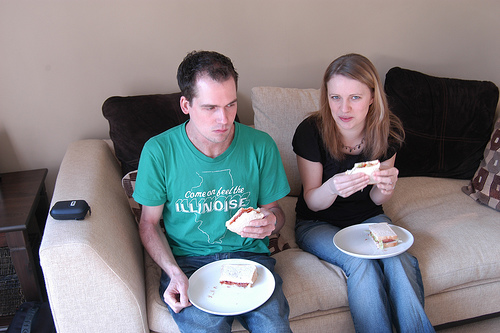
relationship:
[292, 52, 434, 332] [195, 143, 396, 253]
woman eating sandwiches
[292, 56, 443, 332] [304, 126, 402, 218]
woman wearing black top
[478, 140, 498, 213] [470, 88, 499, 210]
brown and tan pillow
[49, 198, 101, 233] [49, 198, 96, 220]
black cell phone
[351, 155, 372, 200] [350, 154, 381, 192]
hand holding sandwich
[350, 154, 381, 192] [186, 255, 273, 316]
sandwich on a plate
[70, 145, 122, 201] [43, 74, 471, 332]
cream colored sofa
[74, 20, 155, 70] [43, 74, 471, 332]
white wall behind sofa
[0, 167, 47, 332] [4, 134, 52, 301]
table wooden chest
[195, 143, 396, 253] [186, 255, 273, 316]
sandwiches on a plate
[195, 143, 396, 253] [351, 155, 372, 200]
sandwiches in hand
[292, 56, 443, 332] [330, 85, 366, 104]
woman with blue eyes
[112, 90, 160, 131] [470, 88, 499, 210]
dark chocolate brown soft pillow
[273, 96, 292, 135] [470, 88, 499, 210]
beige soft pillow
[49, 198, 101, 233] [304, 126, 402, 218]
black sleeved shirt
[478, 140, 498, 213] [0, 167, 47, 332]
brown side table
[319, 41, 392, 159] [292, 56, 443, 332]
head of a woman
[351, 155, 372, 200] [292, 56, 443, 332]
hand of woman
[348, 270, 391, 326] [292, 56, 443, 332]
leg of woman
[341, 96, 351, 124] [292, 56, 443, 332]
nose of woman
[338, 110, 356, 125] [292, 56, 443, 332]
mouth of woman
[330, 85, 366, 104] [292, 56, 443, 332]
eyes of woman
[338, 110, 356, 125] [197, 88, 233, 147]
mouth of man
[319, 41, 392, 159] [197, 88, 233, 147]
head of man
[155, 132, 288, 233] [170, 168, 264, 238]
green shirt of illinois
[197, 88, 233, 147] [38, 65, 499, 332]
man on sofa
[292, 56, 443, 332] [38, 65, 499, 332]
woman on sofa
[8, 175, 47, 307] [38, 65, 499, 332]
table next to sofa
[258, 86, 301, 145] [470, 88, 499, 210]
tan colored pillow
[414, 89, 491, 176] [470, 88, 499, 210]
dark soft pillow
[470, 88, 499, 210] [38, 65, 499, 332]
pillow on sofa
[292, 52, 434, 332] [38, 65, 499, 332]
woman sitting on sofa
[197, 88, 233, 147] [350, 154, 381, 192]
man eating sandwich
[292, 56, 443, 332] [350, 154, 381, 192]
woman eating sandwich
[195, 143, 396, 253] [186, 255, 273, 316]
sandwiches on plate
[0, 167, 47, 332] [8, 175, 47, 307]
table wooden table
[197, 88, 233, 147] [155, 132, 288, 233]
man wearing shirt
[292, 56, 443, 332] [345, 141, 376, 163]
woman wearing necklace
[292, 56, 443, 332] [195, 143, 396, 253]
woman holding sandwiches